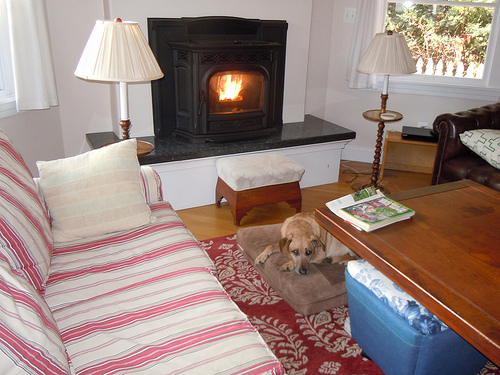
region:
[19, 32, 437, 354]
a living room scene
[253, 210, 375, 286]
a dog on a pillow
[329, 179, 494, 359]
a wooden coffee table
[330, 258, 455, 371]
a blue container under the table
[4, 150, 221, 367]
a pink and white striped couch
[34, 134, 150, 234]
a light pink pillow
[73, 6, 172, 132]
a white lamp in the room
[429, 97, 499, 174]
a brown leather sofa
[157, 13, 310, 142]
a fireplace in the wall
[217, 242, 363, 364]
a maroon rug on the floor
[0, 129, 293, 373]
Striped couch by the wall.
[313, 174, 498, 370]
Wooden end table in the room.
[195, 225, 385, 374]
Rug on the floor.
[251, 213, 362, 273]
Dog on the cushion.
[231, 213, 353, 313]
Brown cushion on the floor.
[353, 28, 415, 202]
Table lamp on the floor.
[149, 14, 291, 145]
Fireplace in the wall.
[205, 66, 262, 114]
Fire burning in the fireplace.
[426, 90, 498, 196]
Brown couch by the window.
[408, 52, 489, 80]
White picket fence outside the window.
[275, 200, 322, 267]
this is a dog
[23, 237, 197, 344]
this is a couch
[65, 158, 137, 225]
this is a pillow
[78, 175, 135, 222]
the pillow is white in color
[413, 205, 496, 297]
this is a table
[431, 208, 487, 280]
the table is brown in color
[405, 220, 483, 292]
the table is wooden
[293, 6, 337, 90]
this is the wall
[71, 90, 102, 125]
the wall is white in color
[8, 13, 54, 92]
this is a curtain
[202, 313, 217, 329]
part of a cloth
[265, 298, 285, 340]
part of a carpet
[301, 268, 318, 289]
part of a cushio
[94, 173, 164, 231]
part of a line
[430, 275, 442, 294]
part of a line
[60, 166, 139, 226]
the seat pillow is white in color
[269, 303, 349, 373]
the carpet is red in color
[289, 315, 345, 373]
the carpet has some white flowers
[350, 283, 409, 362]
the basket is light blue in color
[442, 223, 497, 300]
the table is wooden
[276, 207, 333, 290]
the dog is brown in color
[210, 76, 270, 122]
the fire is yelow in color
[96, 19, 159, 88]
the lamp is beside the couch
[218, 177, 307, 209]
the stool is brown in color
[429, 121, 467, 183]
the couch is dark brown in color